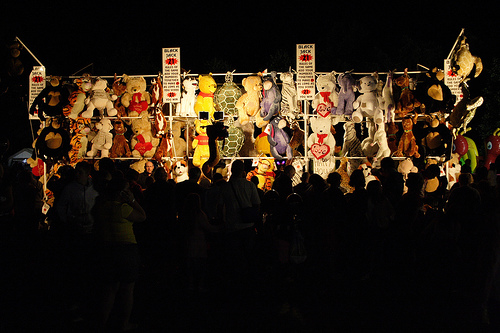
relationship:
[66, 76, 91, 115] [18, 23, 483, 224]
tiger on rack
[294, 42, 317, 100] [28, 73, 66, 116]
sign with animals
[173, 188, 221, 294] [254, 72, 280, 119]
little girl looking at stuffed animal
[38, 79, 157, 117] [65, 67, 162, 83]
animals on rack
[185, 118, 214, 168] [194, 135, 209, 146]
stuffed animal wearing red t-shirt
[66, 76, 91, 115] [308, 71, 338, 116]
tiger standing next to stuffed animal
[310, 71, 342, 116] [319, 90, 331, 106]
white bear wears bow tie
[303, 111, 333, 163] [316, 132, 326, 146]
bear wears bow tie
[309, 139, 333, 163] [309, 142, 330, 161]
heart says heart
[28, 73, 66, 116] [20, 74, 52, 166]
animals on edge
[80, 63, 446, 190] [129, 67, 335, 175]
stuffed animals illuminated by light